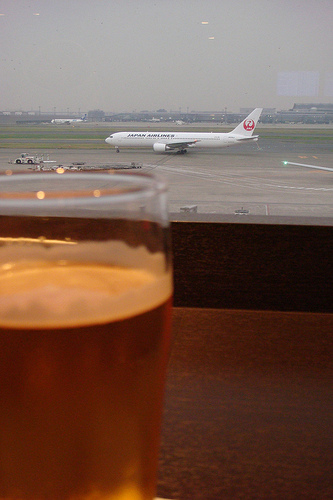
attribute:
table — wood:
[158, 301, 332, 497]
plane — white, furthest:
[46, 112, 87, 127]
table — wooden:
[1, 218, 328, 498]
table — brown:
[176, 274, 331, 498]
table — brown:
[153, 245, 307, 472]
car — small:
[14, 151, 33, 162]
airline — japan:
[104, 105, 265, 153]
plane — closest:
[95, 102, 273, 166]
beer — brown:
[38, 271, 176, 399]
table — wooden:
[181, 310, 332, 495]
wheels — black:
[115, 148, 120, 152]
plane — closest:
[105, 107, 261, 154]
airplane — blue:
[100, 103, 273, 155]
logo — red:
[239, 106, 263, 144]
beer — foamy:
[4, 198, 167, 495]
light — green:
[282, 156, 293, 171]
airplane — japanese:
[135, 124, 249, 150]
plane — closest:
[122, 125, 262, 146]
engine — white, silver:
[158, 139, 173, 158]